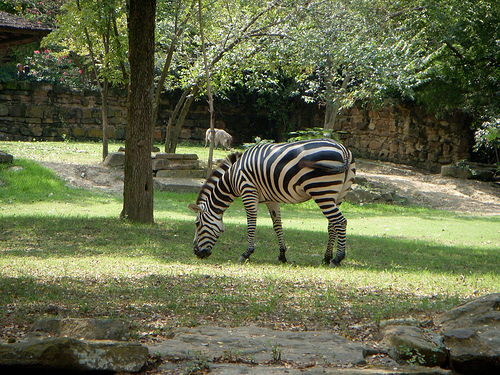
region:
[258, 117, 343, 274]
A zebra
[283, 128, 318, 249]
A zebra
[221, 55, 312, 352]
A zebra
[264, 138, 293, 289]
A zebra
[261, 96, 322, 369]
A zebra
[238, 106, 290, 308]
A zebra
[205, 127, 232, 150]
white animal standing near a stone wall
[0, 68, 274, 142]
stone wall is brown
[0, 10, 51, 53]
a roof is visible behind the stone wall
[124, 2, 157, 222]
tree trunk to the left of zebra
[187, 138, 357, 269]
zebra is eating grass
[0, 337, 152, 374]
gray rock on the grass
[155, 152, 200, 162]
flat gray rock on top of rock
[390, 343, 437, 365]
weeds growing next to a rock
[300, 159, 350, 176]
zebra tail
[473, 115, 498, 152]
white flowering shrub to the right of zebra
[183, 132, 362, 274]
a zebra grazing on grass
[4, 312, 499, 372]
a group of rocks on hillside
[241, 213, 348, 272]
a zebra's feet in field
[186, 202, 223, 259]
a zebra's head eating grass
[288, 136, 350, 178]
a zebra's tail swirling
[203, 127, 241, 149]
a white animal in background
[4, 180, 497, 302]
grassy green field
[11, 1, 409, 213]
a tree in background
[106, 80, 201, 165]
rocks leaning up against a tree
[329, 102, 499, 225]
a dirt path next to a rocky bank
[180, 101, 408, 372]
A zebra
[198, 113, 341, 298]
A zebra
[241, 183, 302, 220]
A zebra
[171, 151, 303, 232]
A zebra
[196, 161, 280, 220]
A zebra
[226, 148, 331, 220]
A zebra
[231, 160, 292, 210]
A zebra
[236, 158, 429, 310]
A zebra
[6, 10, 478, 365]
This is a zoo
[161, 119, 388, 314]
The zebra is eating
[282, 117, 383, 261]
Zebra's tail is to the left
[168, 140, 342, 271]
The zebra is looking downward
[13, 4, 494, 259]
There are a lot of trees here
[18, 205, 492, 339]
The grass has been cut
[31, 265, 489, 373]
There are rocks along the corners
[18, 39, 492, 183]
The walls are the rocks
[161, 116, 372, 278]
The zebra's colors are black and white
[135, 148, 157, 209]
There is a hole in the tree